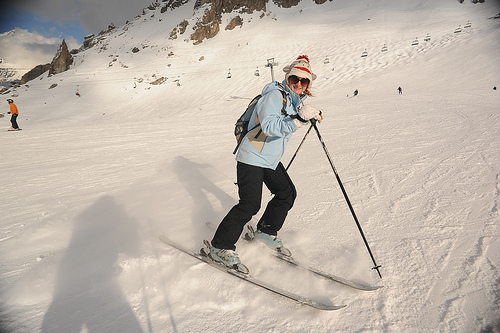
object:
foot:
[243, 227, 297, 256]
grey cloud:
[2, 0, 167, 37]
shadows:
[42, 194, 154, 329]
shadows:
[165, 150, 247, 254]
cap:
[7, 99, 14, 103]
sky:
[0, 0, 163, 51]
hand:
[314, 108, 324, 123]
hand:
[296, 106, 319, 122]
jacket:
[232, 84, 308, 171]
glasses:
[288, 75, 310, 87]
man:
[209, 57, 320, 252]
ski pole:
[284, 113, 324, 181]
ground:
[0, 53, 495, 329]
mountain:
[4, 7, 493, 328]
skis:
[156, 238, 342, 313]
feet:
[200, 242, 243, 270]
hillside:
[82, 41, 227, 130]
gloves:
[317, 109, 323, 123]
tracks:
[403, 181, 498, 331]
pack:
[235, 93, 286, 144]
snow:
[0, 42, 500, 333]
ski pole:
[311, 115, 384, 281]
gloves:
[296, 106, 319, 121]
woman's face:
[289, 76, 309, 94]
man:
[7, 97, 19, 132]